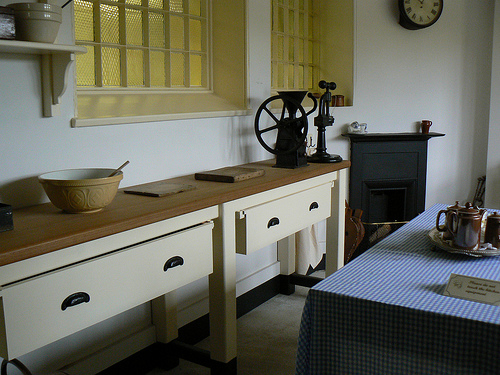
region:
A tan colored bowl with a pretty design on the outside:
[36, 166, 123, 216]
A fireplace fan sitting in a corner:
[343, 193, 364, 264]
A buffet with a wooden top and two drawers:
[0, 147, 352, 373]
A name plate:
[440, 268, 499, 307]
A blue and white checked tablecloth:
[295, 199, 499, 374]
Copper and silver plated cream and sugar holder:
[431, 197, 488, 256]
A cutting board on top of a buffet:
[191, 162, 266, 184]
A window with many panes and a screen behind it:
[73, 0, 208, 88]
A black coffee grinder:
[250, 89, 323, 170]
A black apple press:
[309, 77, 342, 161]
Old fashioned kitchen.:
[11, 11, 498, 370]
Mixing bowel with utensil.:
[33, 163, 139, 222]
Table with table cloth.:
[265, 178, 498, 363]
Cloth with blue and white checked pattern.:
[324, 264, 414, 363]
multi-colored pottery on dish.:
[431, 188, 498, 270]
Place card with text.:
[445, 265, 496, 318]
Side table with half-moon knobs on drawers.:
[11, 142, 336, 372]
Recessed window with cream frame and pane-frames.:
[73, 6, 287, 132]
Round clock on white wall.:
[396, 3, 489, 100]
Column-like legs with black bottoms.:
[154, 287, 250, 371]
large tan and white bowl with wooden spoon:
[34, 157, 143, 214]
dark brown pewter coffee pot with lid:
[435, 196, 486, 252]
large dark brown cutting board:
[193, 162, 269, 189]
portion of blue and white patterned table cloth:
[303, 248, 440, 335]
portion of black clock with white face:
[380, 0, 460, 32]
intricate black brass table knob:
[52, 290, 105, 312]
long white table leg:
[220, 200, 244, 367]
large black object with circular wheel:
[253, 80, 314, 168]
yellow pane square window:
[79, 5, 226, 107]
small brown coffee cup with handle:
[415, 115, 439, 138]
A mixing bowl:
[30, 152, 155, 214]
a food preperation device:
[245, 52, 345, 182]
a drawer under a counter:
[2, 198, 220, 363]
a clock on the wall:
[385, 0, 450, 45]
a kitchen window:
[62, 2, 249, 128]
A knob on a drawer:
[55, 278, 97, 314]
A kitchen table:
[280, 207, 497, 367]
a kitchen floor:
[65, 257, 341, 369]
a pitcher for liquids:
[430, 195, 485, 257]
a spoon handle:
[102, 151, 133, 176]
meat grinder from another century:
[252, 82, 321, 170]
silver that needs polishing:
[425, 195, 497, 262]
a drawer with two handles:
[237, 182, 337, 258]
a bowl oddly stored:
[32, 140, 135, 246]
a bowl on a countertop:
[27, 137, 139, 242]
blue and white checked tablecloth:
[310, 196, 497, 328]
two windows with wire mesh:
[70, 0, 360, 129]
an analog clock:
[386, 1, 448, 32]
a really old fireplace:
[339, 117, 445, 269]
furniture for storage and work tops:
[0, 147, 349, 373]